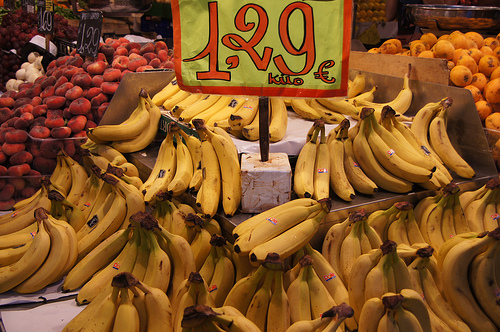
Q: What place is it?
A: It is a market.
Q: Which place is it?
A: It is a market.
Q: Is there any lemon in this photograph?
A: Yes, there are lemons.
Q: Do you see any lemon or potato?
A: Yes, there are lemons.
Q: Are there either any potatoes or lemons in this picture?
A: Yes, there are lemons.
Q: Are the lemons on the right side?
A: Yes, the lemons are on the right of the image.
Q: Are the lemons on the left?
A: No, the lemons are on the right of the image.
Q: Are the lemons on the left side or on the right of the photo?
A: The lemons are on the right of the image.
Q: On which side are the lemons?
A: The lemons are on the right of the image.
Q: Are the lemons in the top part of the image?
A: Yes, the lemons are in the top of the image.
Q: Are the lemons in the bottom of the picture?
A: No, the lemons are in the top of the image.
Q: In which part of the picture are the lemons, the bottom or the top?
A: The lemons are in the top of the image.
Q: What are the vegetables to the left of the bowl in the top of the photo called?
A: The vegetables are lemons.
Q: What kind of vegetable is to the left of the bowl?
A: The vegetables are lemons.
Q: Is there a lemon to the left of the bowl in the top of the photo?
A: Yes, there are lemons to the left of the bowl.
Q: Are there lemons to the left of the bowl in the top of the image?
A: Yes, there are lemons to the left of the bowl.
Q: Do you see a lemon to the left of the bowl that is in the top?
A: Yes, there are lemons to the left of the bowl.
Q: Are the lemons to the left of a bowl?
A: Yes, the lemons are to the left of a bowl.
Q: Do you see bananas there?
A: Yes, there is a banana.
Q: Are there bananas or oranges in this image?
A: Yes, there is a banana.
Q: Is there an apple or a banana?
A: Yes, there are bananas.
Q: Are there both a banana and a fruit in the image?
A: Yes, there are both a banana and a fruit.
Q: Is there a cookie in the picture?
A: No, there are no cookies.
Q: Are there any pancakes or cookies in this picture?
A: No, there are no cookies or pancakes.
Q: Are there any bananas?
A: Yes, there is a banana.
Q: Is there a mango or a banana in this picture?
A: Yes, there is a banana.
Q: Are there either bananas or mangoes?
A: Yes, there is a banana.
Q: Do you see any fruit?
A: Yes, there is a fruit.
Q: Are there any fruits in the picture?
A: Yes, there is a fruit.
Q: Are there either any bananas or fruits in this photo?
A: Yes, there is a fruit.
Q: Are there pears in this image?
A: Yes, there are pears.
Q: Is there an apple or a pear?
A: Yes, there are pears.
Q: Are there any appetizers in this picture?
A: No, there are no appetizers.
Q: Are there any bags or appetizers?
A: No, there are no appetizers or bags.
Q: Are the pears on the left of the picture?
A: Yes, the pears are on the left of the image.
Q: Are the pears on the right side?
A: No, the pears are on the left of the image.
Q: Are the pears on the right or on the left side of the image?
A: The pears are on the left of the image.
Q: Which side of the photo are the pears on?
A: The pears are on the left of the image.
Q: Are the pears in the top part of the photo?
A: Yes, the pears are in the top of the image.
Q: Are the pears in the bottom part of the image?
A: No, the pears are in the top of the image.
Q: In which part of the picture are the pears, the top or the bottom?
A: The pears are in the top of the image.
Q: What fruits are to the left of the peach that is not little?
A: The fruits are pears.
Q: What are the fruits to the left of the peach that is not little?
A: The fruits are pears.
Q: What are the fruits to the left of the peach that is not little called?
A: The fruits are pears.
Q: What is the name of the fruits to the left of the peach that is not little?
A: The fruits are pears.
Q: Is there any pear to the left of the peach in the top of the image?
A: Yes, there are pears to the left of the peach.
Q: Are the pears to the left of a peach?
A: Yes, the pears are to the left of a peach.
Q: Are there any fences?
A: No, there are no fences.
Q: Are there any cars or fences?
A: No, there are no fences or cars.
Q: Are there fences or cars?
A: No, there are no fences or cars.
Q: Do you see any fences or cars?
A: No, there are no fences or cars.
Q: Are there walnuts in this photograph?
A: No, there are no walnuts.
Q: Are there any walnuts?
A: No, there are no walnuts.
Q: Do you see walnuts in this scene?
A: No, there are no walnuts.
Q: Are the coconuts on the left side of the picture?
A: Yes, the coconuts are on the left of the image.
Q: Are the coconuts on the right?
A: No, the coconuts are on the left of the image.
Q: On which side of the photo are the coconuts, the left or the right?
A: The coconuts are on the left of the image.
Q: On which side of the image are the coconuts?
A: The coconuts are on the left of the image.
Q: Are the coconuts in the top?
A: Yes, the coconuts are in the top of the image.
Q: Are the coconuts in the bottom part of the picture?
A: No, the coconuts are in the top of the image.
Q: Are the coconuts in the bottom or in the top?
A: The coconuts are in the top of the image.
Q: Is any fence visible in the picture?
A: No, there are no fences.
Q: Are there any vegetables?
A: Yes, there are vegetables.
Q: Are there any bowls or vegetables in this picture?
A: Yes, there are vegetables.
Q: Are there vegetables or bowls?
A: Yes, there are vegetables.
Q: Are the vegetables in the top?
A: Yes, the vegetables are in the top of the image.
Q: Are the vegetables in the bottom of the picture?
A: No, the vegetables are in the top of the image.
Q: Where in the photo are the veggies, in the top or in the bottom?
A: The veggies are in the top of the image.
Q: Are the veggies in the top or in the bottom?
A: The veggies are in the top of the image.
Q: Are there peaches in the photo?
A: Yes, there is a peach.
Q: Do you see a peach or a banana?
A: Yes, there is a peach.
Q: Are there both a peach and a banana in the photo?
A: Yes, there are both a peach and a banana.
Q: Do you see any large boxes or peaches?
A: Yes, there is a large peach.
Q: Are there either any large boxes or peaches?
A: Yes, there is a large peach.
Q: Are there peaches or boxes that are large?
A: Yes, the peach is large.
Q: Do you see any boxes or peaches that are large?
A: Yes, the peach is large.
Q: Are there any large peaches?
A: Yes, there is a large peach.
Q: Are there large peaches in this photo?
A: Yes, there is a large peach.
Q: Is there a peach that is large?
A: Yes, there is a peach that is large.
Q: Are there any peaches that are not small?
A: Yes, there is a large peach.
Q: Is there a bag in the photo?
A: No, there are no bags.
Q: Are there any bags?
A: No, there are no bags.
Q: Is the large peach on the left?
A: Yes, the peach is on the left of the image.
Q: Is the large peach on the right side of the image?
A: No, the peach is on the left of the image.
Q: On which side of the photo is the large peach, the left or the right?
A: The peach is on the left of the image.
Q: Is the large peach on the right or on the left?
A: The peach is on the left of the image.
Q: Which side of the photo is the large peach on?
A: The peach is on the left of the image.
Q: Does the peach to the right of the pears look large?
A: Yes, the peach is large.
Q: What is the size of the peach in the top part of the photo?
A: The peach is large.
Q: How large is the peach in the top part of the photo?
A: The peach is large.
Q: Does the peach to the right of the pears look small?
A: No, the peach is large.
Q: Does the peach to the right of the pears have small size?
A: No, the peach is large.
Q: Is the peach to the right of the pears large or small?
A: The peach is large.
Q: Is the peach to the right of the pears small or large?
A: The peach is large.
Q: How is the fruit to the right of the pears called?
A: The fruit is a peach.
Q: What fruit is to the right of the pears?
A: The fruit is a peach.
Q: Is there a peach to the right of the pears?
A: Yes, there is a peach to the right of the pears.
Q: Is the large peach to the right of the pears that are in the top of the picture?
A: Yes, the peach is to the right of the pears.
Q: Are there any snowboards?
A: No, there are no snowboards.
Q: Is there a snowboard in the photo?
A: No, there are no snowboards.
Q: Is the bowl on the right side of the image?
A: Yes, the bowl is on the right of the image.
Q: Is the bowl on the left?
A: No, the bowl is on the right of the image.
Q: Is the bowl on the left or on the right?
A: The bowl is on the right of the image.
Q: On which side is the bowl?
A: The bowl is on the right of the image.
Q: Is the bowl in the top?
A: Yes, the bowl is in the top of the image.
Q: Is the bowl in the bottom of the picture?
A: No, the bowl is in the top of the image.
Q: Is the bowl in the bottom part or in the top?
A: The bowl is in the top of the image.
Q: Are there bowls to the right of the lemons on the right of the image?
A: Yes, there is a bowl to the right of the lemons.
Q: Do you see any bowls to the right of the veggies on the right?
A: Yes, there is a bowl to the right of the lemons.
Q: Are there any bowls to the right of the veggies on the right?
A: Yes, there is a bowl to the right of the lemons.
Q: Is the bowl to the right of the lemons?
A: Yes, the bowl is to the right of the lemons.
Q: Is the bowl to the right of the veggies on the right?
A: Yes, the bowl is to the right of the lemons.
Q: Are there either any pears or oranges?
A: Yes, there are oranges.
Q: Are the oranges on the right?
A: Yes, the oranges are on the right of the image.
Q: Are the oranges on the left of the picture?
A: No, the oranges are on the right of the image.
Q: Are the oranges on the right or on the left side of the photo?
A: The oranges are on the right of the image.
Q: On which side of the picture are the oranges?
A: The oranges are on the right of the image.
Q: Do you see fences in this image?
A: No, there are no fences.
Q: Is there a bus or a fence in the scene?
A: No, there are no fences or buses.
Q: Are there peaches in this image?
A: Yes, there are peaches.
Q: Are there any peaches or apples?
A: Yes, there are peaches.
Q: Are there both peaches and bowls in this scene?
A: Yes, there are both peaches and a bowl.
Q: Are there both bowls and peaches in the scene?
A: Yes, there are both peaches and a bowl.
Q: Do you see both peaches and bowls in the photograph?
A: Yes, there are both peaches and a bowl.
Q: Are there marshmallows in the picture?
A: No, there are no marshmallows.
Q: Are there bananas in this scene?
A: Yes, there is a banana.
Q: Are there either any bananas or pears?
A: Yes, there is a banana.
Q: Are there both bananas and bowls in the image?
A: Yes, there are both a banana and a bowl.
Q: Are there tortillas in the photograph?
A: No, there are no tortillas.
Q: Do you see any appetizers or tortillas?
A: No, there are no tortillas or appetizers.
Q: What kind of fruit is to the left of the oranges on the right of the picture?
A: The fruit is a banana.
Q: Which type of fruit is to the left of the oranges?
A: The fruit is a banana.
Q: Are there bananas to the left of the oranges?
A: Yes, there is a banana to the left of the oranges.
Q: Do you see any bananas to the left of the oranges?
A: Yes, there is a banana to the left of the oranges.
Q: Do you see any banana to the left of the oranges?
A: Yes, there is a banana to the left of the oranges.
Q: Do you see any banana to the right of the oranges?
A: No, the banana is to the left of the oranges.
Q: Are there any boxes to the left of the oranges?
A: No, there is a banana to the left of the oranges.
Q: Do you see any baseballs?
A: No, there are no baseballs.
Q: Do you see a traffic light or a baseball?
A: No, there are no baseballs or traffic lights.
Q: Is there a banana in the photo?
A: Yes, there is a banana.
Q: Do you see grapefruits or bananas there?
A: Yes, there is a banana.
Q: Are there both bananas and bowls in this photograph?
A: Yes, there are both a banana and a bowl.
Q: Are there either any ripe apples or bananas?
A: Yes, there is a ripe banana.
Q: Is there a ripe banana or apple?
A: Yes, there is a ripe banana.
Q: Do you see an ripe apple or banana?
A: Yes, there is a ripe banana.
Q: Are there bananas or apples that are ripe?
A: Yes, the banana is ripe.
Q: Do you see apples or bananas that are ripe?
A: Yes, the banana is ripe.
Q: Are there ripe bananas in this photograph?
A: Yes, there is a ripe banana.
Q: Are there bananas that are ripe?
A: Yes, there is a banana that is ripe.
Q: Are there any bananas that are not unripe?
A: Yes, there is an ripe banana.